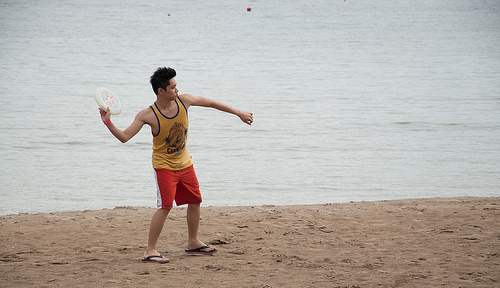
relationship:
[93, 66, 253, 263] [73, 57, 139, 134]
man with frisbee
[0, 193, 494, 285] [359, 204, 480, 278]
footprints on sand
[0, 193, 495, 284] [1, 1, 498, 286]
sand on beach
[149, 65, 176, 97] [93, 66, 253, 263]
hair on man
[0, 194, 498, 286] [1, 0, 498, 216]
dirt by water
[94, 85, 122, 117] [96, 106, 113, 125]
frisbee in man`s hand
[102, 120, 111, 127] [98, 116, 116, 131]
band on wrist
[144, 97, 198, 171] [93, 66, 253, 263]
shirt on man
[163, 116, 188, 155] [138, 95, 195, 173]
picture on shirt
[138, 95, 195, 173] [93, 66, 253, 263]
shirt on man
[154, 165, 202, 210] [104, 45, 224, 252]
shorts on man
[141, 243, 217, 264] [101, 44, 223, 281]
flip flops on man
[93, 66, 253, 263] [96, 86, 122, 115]
man throwing frisbee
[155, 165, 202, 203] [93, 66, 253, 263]
shorts on man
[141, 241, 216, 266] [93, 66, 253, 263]
flip flops on man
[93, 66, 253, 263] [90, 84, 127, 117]
man throwing frisbee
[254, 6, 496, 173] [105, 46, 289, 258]
waters behind man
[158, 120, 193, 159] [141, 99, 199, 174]
design on shirt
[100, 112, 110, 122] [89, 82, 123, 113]
hand holding frisbee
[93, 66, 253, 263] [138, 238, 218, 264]
man wearing shoes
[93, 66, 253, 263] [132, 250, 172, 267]
man wearing sandal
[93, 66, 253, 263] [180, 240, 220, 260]
man wearing sandal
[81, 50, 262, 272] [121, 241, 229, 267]
man wearing flipflops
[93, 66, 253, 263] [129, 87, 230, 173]
man wearing shirt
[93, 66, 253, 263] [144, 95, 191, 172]
man wearing shirt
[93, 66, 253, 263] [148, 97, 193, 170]
man wearing tank top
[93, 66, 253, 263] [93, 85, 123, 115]
man holding frisbee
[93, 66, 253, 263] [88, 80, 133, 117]
man holding frisbee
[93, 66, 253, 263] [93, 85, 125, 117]
man playing frisbee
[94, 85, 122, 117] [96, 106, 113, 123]
frisbee in right hand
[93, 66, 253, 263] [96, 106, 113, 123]
man has right hand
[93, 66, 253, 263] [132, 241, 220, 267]
man wearing flip flops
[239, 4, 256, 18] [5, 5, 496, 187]
red buoy in water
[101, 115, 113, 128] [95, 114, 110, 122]
bracelet on wrist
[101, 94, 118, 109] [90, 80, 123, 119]
picture on frisbee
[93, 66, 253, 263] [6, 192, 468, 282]
man on beach